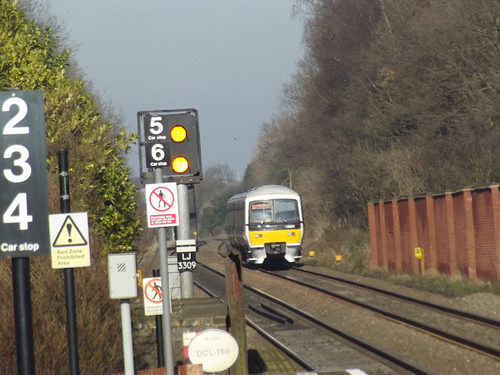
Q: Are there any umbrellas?
A: No, there are no umbrellas.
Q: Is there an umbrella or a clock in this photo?
A: No, there are no umbrellas or clocks.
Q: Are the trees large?
A: Yes, the trees are large.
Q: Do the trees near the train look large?
A: Yes, the trees are large.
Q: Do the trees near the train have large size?
A: Yes, the trees are large.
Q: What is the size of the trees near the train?
A: The trees are large.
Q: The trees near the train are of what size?
A: The trees are large.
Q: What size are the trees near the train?
A: The trees are large.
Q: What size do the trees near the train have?
A: The trees have large size.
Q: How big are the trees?
A: The trees are large.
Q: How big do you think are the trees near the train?
A: The trees are large.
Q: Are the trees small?
A: No, the trees are large.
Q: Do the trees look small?
A: No, the trees are large.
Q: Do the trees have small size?
A: No, the trees are large.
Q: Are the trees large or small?
A: The trees are large.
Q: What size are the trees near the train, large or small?
A: The trees are large.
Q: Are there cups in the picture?
A: No, there are no cups.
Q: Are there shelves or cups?
A: No, there are no cups or shelves.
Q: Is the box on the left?
A: Yes, the box is on the left of the image.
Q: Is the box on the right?
A: No, the box is on the left of the image.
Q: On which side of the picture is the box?
A: The box is on the left of the image.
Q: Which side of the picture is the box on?
A: The box is on the left of the image.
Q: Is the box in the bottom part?
A: Yes, the box is in the bottom of the image.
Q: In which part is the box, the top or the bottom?
A: The box is in the bottom of the image.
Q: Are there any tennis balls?
A: No, there are no tennis balls.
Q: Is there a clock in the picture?
A: No, there are no clocks.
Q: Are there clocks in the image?
A: No, there are no clocks.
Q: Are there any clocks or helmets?
A: No, there are no clocks or helmets.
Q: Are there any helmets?
A: No, there are no helmets.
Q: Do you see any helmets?
A: No, there are no helmets.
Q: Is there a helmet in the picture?
A: No, there are no helmets.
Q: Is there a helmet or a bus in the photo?
A: No, there are no helmets or buses.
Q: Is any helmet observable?
A: No, there are no helmets.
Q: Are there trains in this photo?
A: Yes, there is a train.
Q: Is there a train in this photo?
A: Yes, there is a train.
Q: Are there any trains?
A: Yes, there is a train.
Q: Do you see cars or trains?
A: Yes, there is a train.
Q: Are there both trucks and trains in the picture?
A: No, there is a train but no trucks.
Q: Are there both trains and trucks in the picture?
A: No, there is a train but no trucks.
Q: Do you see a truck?
A: No, there are no trucks.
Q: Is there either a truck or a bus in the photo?
A: No, there are no trucks or buses.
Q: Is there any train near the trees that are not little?
A: Yes, there is a train near the trees.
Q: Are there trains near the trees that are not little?
A: Yes, there is a train near the trees.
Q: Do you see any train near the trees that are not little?
A: Yes, there is a train near the trees.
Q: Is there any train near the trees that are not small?
A: Yes, there is a train near the trees.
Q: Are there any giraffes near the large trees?
A: No, there is a train near the trees.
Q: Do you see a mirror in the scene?
A: No, there are no mirrors.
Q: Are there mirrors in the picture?
A: No, there are no mirrors.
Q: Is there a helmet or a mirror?
A: No, there are no mirrors or helmets.